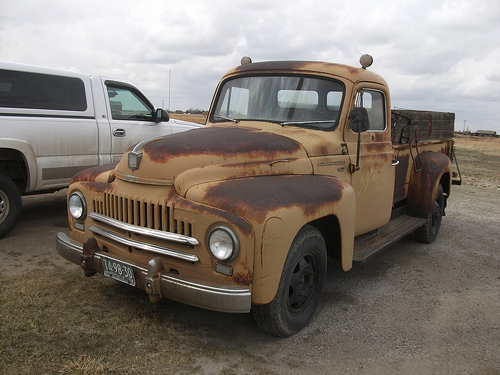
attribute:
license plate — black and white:
[98, 253, 141, 285]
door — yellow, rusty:
[346, 81, 408, 221]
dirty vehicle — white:
[0, 56, 203, 229]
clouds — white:
[0, 1, 496, 105]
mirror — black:
[347, 105, 369, 172]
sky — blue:
[0, 0, 499, 134]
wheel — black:
[249, 220, 329, 339]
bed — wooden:
[370, 75, 485, 225]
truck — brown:
[58, 61, 465, 336]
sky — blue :
[400, 19, 495, 71]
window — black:
[1, 69, 91, 112]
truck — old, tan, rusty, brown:
[47, 47, 462, 344]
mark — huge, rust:
[132, 125, 306, 158]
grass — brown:
[4, 269, 218, 374]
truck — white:
[0, 56, 210, 215]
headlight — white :
[202, 230, 237, 262]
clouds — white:
[152, 16, 232, 63]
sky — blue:
[1, 2, 496, 106]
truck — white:
[5, 61, 206, 201]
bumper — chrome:
[49, 233, 263, 325]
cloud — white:
[0, 0, 500, 134]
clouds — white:
[396, 27, 445, 69]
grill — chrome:
[84, 204, 204, 261]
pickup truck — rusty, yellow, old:
[45, 50, 465, 342]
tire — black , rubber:
[251, 223, 328, 339]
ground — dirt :
[3, 159, 498, 370]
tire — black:
[282, 225, 336, 326]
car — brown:
[49, 44, 465, 336]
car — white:
[0, 66, 204, 233]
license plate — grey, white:
[97, 248, 145, 296]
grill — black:
[74, 185, 205, 252]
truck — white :
[5, 47, 238, 176]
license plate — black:
[99, 255, 137, 290]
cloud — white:
[129, 0, 485, 78]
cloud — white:
[98, 58, 223, 119]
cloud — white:
[0, 0, 185, 85]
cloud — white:
[392, 52, 497, 134]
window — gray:
[352, 82, 387, 131]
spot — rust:
[203, 169, 343, 218]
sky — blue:
[98, 0, 454, 89]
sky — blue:
[4, 5, 482, 118]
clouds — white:
[3, 4, 494, 117]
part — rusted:
[412, 147, 451, 220]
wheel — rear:
[413, 178, 447, 243]